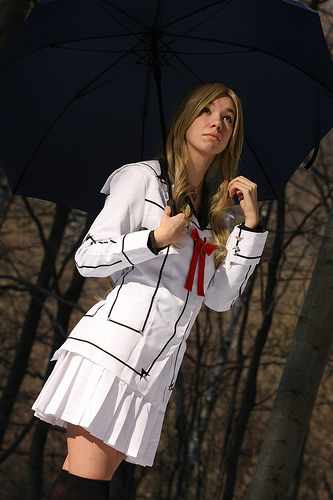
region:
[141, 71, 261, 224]
woman with light brown hair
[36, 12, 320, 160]
blue umbrella over woman's head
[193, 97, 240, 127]
woman's eyes looking up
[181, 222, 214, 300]
red bow woman's jacket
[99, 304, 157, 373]
black lines on white jacket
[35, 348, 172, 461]
pleated white skirt on girl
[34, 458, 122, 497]
black nylon stockings on thigh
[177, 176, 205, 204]
jewelry on woman's neck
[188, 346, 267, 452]
trees with thin trunks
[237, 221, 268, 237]
black shirt cuff under jacket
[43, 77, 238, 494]
this is a woman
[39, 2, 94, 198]
this is an umbrella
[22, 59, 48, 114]
the umbrella is black in color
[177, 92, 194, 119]
the woman's hair is blonde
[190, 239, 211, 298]
this is a bow tie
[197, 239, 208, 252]
the bow tie is red in color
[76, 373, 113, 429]
this is a skirt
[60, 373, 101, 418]
the skirt is white in color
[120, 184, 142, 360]
the blouse is white in color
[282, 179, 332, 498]
this is a tree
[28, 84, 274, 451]
woman posing for photo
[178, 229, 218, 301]
red bow on outfit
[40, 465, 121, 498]
black knee high socks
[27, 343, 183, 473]
white pleated skirt of model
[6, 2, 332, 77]
black umbrella model is holding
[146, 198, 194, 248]
right hand holding umbrella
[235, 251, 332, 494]
brown trunk of tree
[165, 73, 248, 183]
face of a blonde model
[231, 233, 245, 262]
buttons of a white jacket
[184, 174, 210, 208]
necklace of a female model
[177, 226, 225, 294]
red bow on her top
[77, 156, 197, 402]
black lining on her top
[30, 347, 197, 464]
pleated white short skirt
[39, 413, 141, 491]
her thigh is exposed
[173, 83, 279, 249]
she has long hair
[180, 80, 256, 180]
she is looking up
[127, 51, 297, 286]
she is holding a black umbrella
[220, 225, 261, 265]
two buttons on her sleeve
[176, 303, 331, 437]
trees behind her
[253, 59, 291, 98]
part of an umbrella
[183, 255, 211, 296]
part of a ribbon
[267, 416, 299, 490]
stem of a tree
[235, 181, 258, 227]
part of the left hand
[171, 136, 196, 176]
hair of a lady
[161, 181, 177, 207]
handle of an umbrella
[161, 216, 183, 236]
part of the right hand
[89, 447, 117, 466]
part of a knee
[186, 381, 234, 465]
part of some trees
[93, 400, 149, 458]
part of a white dress